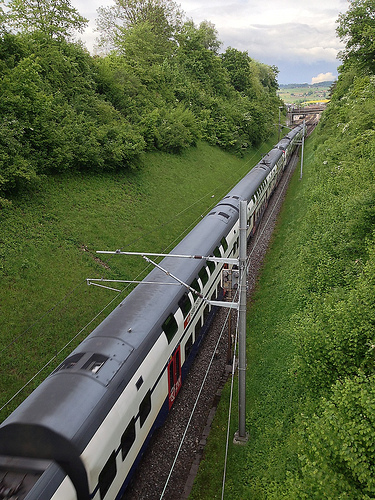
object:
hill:
[0, 99, 286, 421]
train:
[0, 120, 312, 499]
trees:
[0, 0, 285, 203]